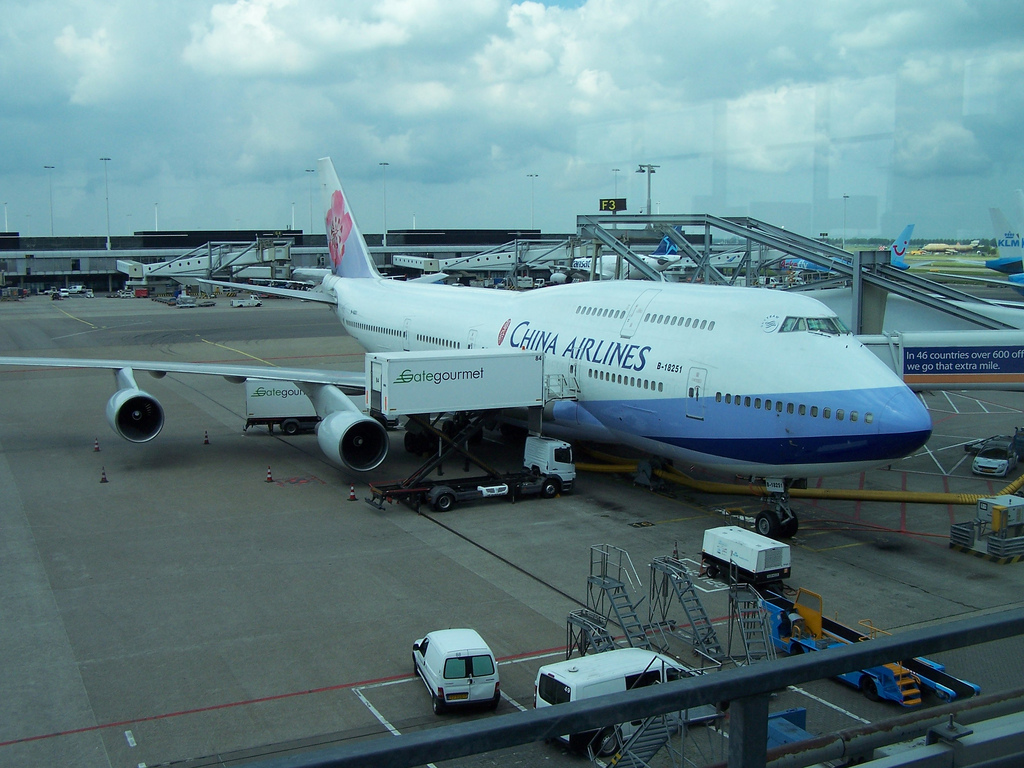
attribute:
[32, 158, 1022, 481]
airplane — white, parked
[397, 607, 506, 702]
van — small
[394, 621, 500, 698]
van — small, white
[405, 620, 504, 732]
van — white, small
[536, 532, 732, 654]
stairs — rolling